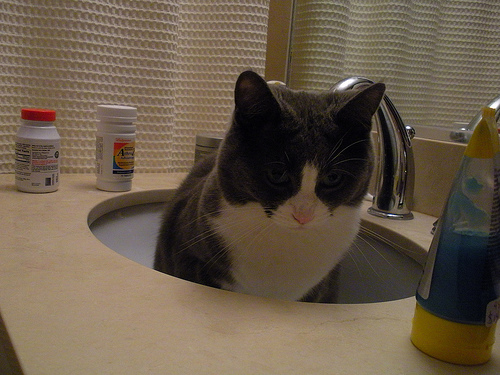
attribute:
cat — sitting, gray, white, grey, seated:
[155, 68, 389, 301]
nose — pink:
[290, 199, 318, 228]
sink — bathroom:
[87, 189, 428, 305]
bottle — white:
[93, 101, 137, 194]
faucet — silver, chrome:
[326, 72, 416, 222]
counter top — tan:
[2, 177, 499, 373]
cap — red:
[18, 106, 60, 125]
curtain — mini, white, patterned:
[2, 2, 274, 175]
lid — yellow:
[408, 299, 498, 368]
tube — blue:
[414, 95, 499, 330]